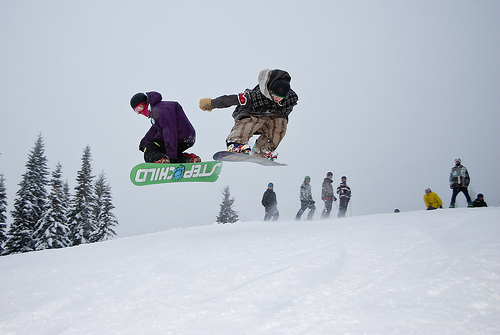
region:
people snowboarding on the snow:
[44, 22, 312, 239]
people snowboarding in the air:
[69, 38, 423, 276]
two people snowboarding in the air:
[112, 31, 309, 198]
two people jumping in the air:
[60, 21, 332, 265]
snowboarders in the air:
[129, 9, 294, 178]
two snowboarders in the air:
[104, 44, 374, 248]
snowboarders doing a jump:
[91, 55, 297, 177]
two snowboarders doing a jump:
[102, 20, 404, 250]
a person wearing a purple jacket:
[64, 18, 360, 215]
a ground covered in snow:
[360, 223, 431, 315]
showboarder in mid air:
[119, 89, 221, 192]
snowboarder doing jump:
[198, 57, 299, 175]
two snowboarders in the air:
[121, 60, 303, 196]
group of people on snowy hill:
[251, 155, 499, 229]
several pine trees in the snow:
[8, 128, 117, 271]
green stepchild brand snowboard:
[126, 153, 226, 185]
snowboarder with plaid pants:
[197, 65, 303, 171]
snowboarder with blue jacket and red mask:
[122, 81, 221, 188]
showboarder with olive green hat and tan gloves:
[198, 55, 298, 177]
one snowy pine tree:
[213, 183, 244, 230]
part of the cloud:
[430, 115, 437, 132]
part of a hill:
[311, 253, 318, 292]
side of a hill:
[271, 241, 283, 256]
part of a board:
[198, 173, 206, 184]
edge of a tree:
[91, 248, 106, 265]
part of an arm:
[435, 196, 442, 211]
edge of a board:
[218, 173, 222, 177]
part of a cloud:
[386, 75, 391, 76]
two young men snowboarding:
[83, 53, 330, 216]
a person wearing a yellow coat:
[420, 179, 440, 213]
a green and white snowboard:
[137, 154, 213, 191]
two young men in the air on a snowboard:
[112, 64, 329, 204]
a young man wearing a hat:
[267, 67, 303, 109]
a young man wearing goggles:
[122, 97, 147, 118]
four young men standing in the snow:
[248, 170, 363, 233]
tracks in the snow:
[131, 222, 443, 322]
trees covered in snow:
[8, 133, 118, 285]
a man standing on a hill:
[442, 149, 472, 211]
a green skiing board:
[131, 165, 223, 185]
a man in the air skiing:
[126, 90, 203, 188]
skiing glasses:
[134, 103, 143, 113]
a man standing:
[449, 155, 471, 206]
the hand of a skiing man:
[198, 97, 243, 108]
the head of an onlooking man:
[327, 172, 333, 179]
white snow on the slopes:
[170, 255, 345, 319]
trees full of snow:
[8, 143, 112, 243]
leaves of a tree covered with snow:
[40, 221, 65, 246]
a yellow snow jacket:
[424, 193, 441, 206]